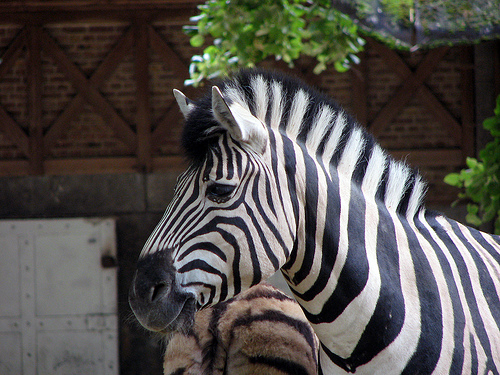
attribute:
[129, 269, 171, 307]
snout — black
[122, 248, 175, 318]
nose — black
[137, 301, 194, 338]
mouth — black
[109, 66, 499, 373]
zebra — stripes, black, white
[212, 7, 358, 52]
leaves — green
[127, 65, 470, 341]
zebra — black, white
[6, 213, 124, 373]
door — white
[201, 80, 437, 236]
zebra — one, big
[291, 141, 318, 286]
stripe — black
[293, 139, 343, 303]
stripe — black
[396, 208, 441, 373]
stripe — black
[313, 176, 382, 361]
stripe — white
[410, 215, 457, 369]
stripe — white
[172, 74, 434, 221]
mane — white, black